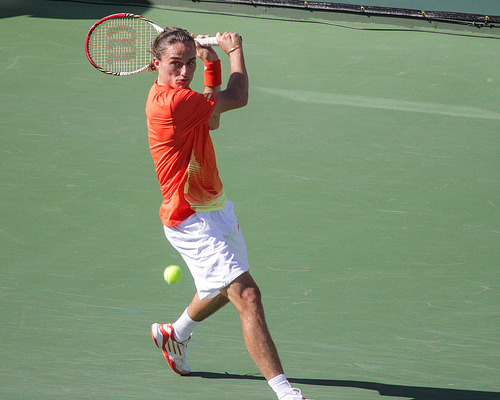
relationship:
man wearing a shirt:
[101, 15, 277, 224] [132, 79, 228, 228]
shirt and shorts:
[132, 79, 228, 228] [148, 188, 273, 337]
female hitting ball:
[145, 25, 311, 399] [144, 252, 225, 308]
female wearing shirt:
[145, 25, 311, 399] [132, 82, 231, 215]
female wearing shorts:
[145, 25, 311, 399] [169, 211, 236, 308]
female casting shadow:
[145, 25, 311, 399] [178, 369, 481, 398]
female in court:
[130, 13, 310, 398] [10, 5, 13, 12]